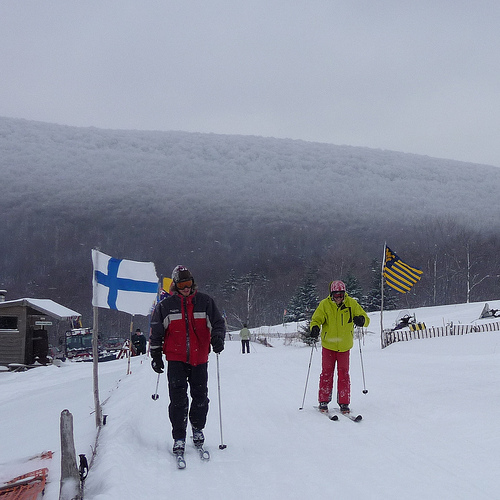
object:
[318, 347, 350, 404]
pants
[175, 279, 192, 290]
goggles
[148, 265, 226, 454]
man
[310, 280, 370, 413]
man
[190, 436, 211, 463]
ski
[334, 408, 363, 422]
ski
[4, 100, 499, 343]
mountain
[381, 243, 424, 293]
flag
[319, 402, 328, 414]
foot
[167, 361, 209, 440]
pants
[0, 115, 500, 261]
brocolli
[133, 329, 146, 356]
people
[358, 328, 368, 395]
pole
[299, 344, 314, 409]
pole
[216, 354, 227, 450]
pole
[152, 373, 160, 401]
pole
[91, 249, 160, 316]
flag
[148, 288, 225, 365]
coat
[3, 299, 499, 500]
white snow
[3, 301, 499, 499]
hill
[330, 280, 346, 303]
helmet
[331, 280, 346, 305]
head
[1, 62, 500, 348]
background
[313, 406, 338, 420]
ski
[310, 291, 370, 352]
coat